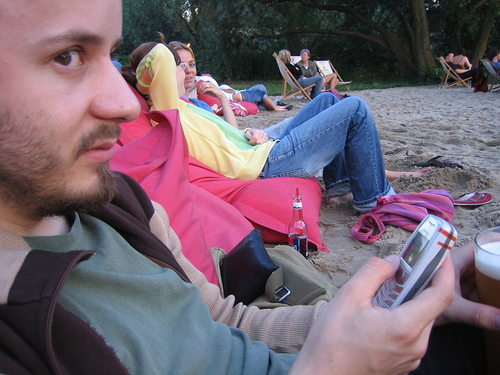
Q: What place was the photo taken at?
A: It was taken at the beach.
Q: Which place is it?
A: It is a beach.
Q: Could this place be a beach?
A: Yes, it is a beach.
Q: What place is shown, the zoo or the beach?
A: It is the beach.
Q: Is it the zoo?
A: No, it is the beach.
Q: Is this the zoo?
A: No, it is the beach.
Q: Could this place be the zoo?
A: No, it is the beach.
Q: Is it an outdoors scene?
A: Yes, it is outdoors.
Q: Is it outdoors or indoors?
A: It is outdoors.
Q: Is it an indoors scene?
A: No, it is outdoors.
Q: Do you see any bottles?
A: Yes, there is a bottle.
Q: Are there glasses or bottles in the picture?
A: Yes, there is a bottle.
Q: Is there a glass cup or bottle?
A: Yes, there is a glass bottle.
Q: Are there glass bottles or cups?
A: Yes, there is a glass bottle.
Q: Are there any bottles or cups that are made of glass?
A: Yes, the bottle is made of glass.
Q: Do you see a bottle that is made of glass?
A: Yes, there is a bottle that is made of glass.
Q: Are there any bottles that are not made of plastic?
A: Yes, there is a bottle that is made of glass.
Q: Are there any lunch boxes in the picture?
A: No, there are no lunch boxes.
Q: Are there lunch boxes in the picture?
A: No, there are no lunch boxes.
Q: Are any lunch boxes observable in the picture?
A: No, there are no lunch boxes.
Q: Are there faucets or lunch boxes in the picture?
A: No, there are no lunch boxes or faucets.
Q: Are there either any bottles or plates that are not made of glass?
A: No, there is a bottle but it is made of glass.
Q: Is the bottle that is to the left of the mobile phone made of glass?
A: Yes, the bottle is made of glass.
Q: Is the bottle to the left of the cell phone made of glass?
A: Yes, the bottle is made of glass.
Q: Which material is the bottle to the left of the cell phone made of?
A: The bottle is made of glass.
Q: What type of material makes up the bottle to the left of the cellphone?
A: The bottle is made of glass.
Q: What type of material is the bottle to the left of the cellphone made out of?
A: The bottle is made of glass.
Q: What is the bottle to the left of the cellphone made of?
A: The bottle is made of glass.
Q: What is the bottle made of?
A: The bottle is made of glass.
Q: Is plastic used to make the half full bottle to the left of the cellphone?
A: No, the bottle is made of glass.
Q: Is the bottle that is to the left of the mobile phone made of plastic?
A: No, the bottle is made of glass.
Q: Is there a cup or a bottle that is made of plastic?
A: No, there is a bottle but it is made of glass.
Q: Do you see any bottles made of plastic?
A: No, there is a bottle but it is made of glass.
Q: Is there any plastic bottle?
A: No, there is a bottle but it is made of glass.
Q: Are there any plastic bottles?
A: No, there is a bottle but it is made of glass.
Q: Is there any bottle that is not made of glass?
A: No, there is a bottle but it is made of glass.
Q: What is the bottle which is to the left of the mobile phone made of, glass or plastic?
A: The bottle is made of glass.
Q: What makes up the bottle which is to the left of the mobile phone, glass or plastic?
A: The bottle is made of glass.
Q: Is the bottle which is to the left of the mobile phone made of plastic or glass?
A: The bottle is made of glass.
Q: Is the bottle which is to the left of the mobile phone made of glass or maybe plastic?
A: The bottle is made of glass.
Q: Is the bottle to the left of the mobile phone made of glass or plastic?
A: The bottle is made of glass.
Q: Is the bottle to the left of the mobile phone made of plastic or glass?
A: The bottle is made of glass.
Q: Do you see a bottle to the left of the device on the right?
A: Yes, there is a bottle to the left of the mobile phone.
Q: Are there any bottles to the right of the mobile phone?
A: No, the bottle is to the left of the mobile phone.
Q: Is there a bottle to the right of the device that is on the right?
A: No, the bottle is to the left of the mobile phone.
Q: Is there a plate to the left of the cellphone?
A: No, there is a bottle to the left of the cellphone.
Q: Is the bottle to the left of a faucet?
A: No, the bottle is to the left of the cell phone.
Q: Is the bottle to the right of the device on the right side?
A: No, the bottle is to the left of the cellphone.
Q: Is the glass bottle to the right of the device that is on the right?
A: No, the bottle is to the left of the cellphone.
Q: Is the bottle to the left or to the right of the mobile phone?
A: The bottle is to the left of the mobile phone.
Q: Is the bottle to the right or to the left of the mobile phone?
A: The bottle is to the left of the mobile phone.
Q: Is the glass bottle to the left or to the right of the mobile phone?
A: The bottle is to the left of the mobile phone.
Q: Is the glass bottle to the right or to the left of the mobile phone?
A: The bottle is to the left of the mobile phone.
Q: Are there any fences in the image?
A: No, there are no fences.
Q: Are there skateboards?
A: No, there are no skateboards.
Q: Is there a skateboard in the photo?
A: No, there are no skateboards.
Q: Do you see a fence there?
A: No, there are no fences.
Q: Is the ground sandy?
A: Yes, the ground is sandy.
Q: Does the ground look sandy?
A: Yes, the ground is sandy.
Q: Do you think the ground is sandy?
A: Yes, the ground is sandy.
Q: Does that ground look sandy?
A: Yes, the ground is sandy.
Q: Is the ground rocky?
A: No, the ground is sandy.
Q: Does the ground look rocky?
A: No, the ground is sandy.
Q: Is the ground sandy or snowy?
A: The ground is sandy.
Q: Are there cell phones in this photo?
A: Yes, there is a cell phone.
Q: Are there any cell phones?
A: Yes, there is a cell phone.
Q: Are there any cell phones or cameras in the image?
A: Yes, there is a cell phone.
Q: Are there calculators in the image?
A: No, there are no calculators.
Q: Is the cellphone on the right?
A: Yes, the cellphone is on the right of the image.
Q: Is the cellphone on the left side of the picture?
A: No, the cellphone is on the right of the image.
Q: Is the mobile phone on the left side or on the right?
A: The mobile phone is on the right of the image.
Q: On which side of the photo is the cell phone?
A: The cell phone is on the right of the image.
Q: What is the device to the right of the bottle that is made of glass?
A: The device is a cell phone.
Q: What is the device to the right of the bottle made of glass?
A: The device is a cell phone.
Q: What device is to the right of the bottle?
A: The device is a cell phone.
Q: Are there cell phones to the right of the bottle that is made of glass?
A: Yes, there is a cell phone to the right of the bottle.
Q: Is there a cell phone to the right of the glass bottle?
A: Yes, there is a cell phone to the right of the bottle.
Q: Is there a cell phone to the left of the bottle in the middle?
A: No, the cell phone is to the right of the bottle.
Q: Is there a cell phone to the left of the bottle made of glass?
A: No, the cell phone is to the right of the bottle.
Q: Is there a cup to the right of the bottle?
A: No, there is a cell phone to the right of the bottle.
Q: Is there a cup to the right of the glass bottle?
A: No, there is a cell phone to the right of the bottle.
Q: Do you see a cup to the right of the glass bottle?
A: No, there is a cell phone to the right of the bottle.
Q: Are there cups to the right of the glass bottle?
A: No, there is a cell phone to the right of the bottle.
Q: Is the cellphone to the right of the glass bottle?
A: Yes, the cellphone is to the right of the bottle.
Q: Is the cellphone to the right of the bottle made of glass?
A: Yes, the cellphone is to the right of the bottle.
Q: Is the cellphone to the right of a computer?
A: No, the cellphone is to the right of the bottle.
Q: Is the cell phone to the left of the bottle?
A: No, the cell phone is to the right of the bottle.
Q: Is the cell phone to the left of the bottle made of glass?
A: No, the cell phone is to the right of the bottle.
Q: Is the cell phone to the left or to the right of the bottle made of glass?
A: The cell phone is to the right of the bottle.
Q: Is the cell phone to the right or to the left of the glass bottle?
A: The cell phone is to the right of the bottle.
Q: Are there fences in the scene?
A: No, there are no fences.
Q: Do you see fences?
A: No, there are no fences.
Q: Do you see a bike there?
A: No, there are no bikes.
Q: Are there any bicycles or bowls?
A: No, there are no bicycles or bowls.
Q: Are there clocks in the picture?
A: No, there are no clocks.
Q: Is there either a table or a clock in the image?
A: No, there are no clocks or tables.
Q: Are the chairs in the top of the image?
A: Yes, the chairs are in the top of the image.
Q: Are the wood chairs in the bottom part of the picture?
A: No, the chairs are in the top of the image.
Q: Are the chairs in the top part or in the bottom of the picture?
A: The chairs are in the top of the image.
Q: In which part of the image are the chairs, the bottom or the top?
A: The chairs are in the top of the image.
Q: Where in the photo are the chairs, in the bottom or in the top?
A: The chairs are in the top of the image.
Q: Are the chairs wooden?
A: Yes, the chairs are wooden.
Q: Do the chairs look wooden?
A: Yes, the chairs are wooden.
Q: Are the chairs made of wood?
A: Yes, the chairs are made of wood.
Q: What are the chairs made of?
A: The chairs are made of wood.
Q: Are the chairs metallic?
A: No, the chairs are wooden.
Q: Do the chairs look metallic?
A: No, the chairs are wooden.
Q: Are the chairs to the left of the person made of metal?
A: No, the chairs are made of wood.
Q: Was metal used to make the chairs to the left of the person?
A: No, the chairs are made of wood.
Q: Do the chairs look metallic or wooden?
A: The chairs are wooden.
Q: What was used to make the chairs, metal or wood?
A: The chairs are made of wood.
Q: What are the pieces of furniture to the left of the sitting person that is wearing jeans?
A: The pieces of furniture are chairs.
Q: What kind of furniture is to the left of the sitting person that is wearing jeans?
A: The pieces of furniture are chairs.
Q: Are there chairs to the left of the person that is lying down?
A: Yes, there are chairs to the left of the person.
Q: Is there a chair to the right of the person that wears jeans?
A: No, the chairs are to the left of the person.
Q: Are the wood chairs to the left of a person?
A: Yes, the chairs are to the left of a person.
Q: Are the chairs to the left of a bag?
A: No, the chairs are to the left of a person.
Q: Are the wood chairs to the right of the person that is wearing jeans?
A: No, the chairs are to the left of the person.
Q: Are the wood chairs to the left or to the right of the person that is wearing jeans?
A: The chairs are to the left of the person.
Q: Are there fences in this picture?
A: No, there are no fences.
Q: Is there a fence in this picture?
A: No, there are no fences.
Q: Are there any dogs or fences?
A: No, there are no fences or dogs.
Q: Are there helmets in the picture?
A: No, there are no helmets.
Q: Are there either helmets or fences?
A: No, there are no helmets or fences.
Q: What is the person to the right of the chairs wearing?
A: The person is wearing jeans.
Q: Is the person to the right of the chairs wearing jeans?
A: Yes, the person is wearing jeans.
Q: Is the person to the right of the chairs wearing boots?
A: No, the person is wearing jeans.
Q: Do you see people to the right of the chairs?
A: Yes, there is a person to the right of the chairs.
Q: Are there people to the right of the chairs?
A: Yes, there is a person to the right of the chairs.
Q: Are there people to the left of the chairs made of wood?
A: No, the person is to the right of the chairs.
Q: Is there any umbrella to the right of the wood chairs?
A: No, there is a person to the right of the chairs.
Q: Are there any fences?
A: No, there are no fences.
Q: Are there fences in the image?
A: No, there are no fences.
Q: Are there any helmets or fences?
A: No, there are no fences or helmets.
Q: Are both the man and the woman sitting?
A: Yes, both the man and the woman are sitting.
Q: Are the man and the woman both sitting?
A: Yes, both the man and the woman are sitting.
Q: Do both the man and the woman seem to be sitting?
A: Yes, both the man and the woman are sitting.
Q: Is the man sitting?
A: Yes, the man is sitting.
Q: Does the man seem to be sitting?
A: Yes, the man is sitting.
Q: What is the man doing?
A: The man is sitting.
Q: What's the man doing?
A: The man is sitting.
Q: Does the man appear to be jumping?
A: No, the man is sitting.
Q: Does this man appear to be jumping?
A: No, the man is sitting.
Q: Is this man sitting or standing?
A: The man is sitting.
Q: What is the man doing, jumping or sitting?
A: The man is sitting.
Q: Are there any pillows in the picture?
A: Yes, there is a pillow.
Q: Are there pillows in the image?
A: Yes, there is a pillow.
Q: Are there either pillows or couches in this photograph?
A: Yes, there is a pillow.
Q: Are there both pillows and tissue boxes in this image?
A: No, there is a pillow but no tissue boxes.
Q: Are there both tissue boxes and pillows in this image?
A: No, there is a pillow but no tissue boxes.